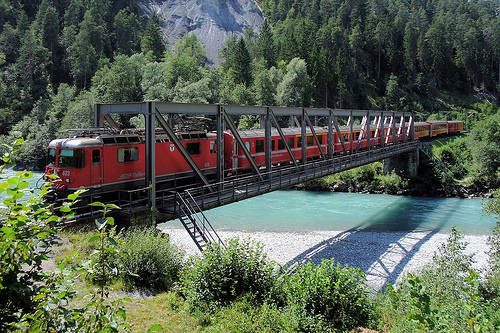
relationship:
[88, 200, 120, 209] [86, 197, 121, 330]
green leaf on plant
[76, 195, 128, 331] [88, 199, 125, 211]
plant has leaf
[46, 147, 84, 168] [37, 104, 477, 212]
window on train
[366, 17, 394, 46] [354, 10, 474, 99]
leaf on plant